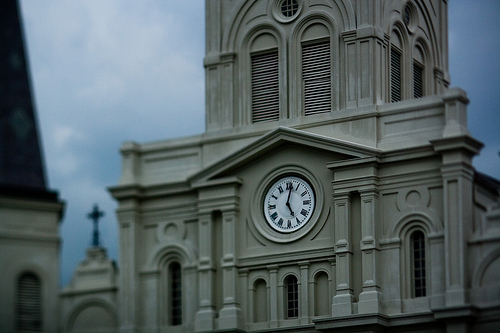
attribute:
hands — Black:
[282, 177, 298, 232]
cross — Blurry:
[85, 204, 106, 246]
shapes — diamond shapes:
[5, 38, 46, 153]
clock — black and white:
[254, 166, 313, 242]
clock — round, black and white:
[251, 163, 331, 245]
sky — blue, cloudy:
[64, 35, 101, 175]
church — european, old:
[3, 3, 498, 330]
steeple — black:
[0, 0, 70, 216]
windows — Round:
[272, 1, 301, 23]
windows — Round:
[400, 1, 418, 33]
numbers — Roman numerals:
[288, 183, 310, 225]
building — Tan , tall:
[102, 0, 499, 330]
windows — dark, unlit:
[250, 271, 321, 304]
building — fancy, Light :
[34, 7, 499, 331]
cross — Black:
[81, 202, 106, 249]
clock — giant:
[251, 169, 336, 236]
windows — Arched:
[409, 232, 424, 298]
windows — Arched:
[286, 279, 297, 316]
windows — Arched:
[166, 261, 182, 321]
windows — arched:
[222, 19, 390, 153]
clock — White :
[267, 175, 318, 235]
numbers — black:
[252, 159, 334, 257]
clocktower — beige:
[104, 0, 498, 331]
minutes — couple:
[284, 179, 300, 209]